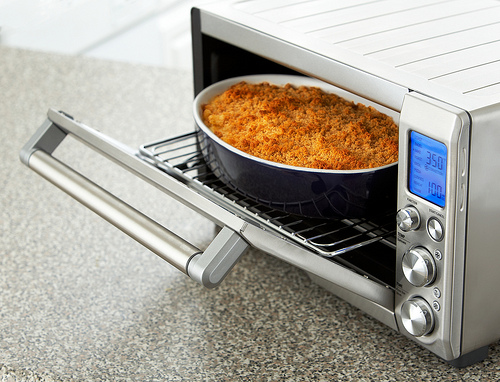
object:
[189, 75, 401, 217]
dish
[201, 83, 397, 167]
food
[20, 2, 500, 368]
oven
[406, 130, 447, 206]
readings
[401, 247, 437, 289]
knob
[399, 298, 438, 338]
knob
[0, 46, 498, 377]
granite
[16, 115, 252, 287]
handle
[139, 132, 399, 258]
grill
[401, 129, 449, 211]
gauge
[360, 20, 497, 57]
indentations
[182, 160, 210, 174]
rack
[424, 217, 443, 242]
button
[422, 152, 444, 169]
350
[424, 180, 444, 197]
100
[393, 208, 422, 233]
dials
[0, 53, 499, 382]
countertop